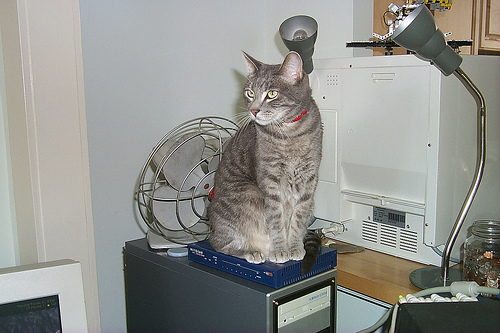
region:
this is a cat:
[191, 39, 353, 288]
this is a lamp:
[384, 5, 469, 95]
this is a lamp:
[262, 3, 351, 88]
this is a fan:
[108, 113, 280, 252]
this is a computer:
[129, 198, 371, 330]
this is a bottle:
[439, 210, 499, 290]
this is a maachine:
[304, 54, 494, 277]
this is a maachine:
[187, 234, 336, 294]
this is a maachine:
[93, 240, 323, 332]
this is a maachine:
[1, 265, 96, 331]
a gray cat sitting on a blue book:
[207, 50, 322, 276]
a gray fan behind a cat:
[131, 115, 241, 249]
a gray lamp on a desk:
[390, 5, 487, 286]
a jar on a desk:
[462, 221, 499, 288]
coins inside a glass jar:
[461, 243, 499, 290]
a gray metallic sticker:
[371, 204, 410, 232]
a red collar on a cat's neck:
[288, 105, 313, 124]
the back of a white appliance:
[311, 55, 498, 266]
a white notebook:
[338, 283, 393, 331]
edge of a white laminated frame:
[3, 260, 88, 332]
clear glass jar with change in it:
[463, 221, 497, 294]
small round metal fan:
[133, 115, 237, 247]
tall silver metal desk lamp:
[389, 3, 485, 289]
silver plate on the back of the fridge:
[371, 204, 404, 227]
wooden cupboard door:
[469, 0, 498, 54]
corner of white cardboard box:
[1, 258, 87, 331]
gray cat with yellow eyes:
[207, 49, 324, 272]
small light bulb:
[293, 29, 306, 38]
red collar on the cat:
[288, 108, 306, 121]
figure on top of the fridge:
[344, 4, 471, 54]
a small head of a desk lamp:
[386, 0, 464, 78]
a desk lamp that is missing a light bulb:
[272, 15, 337, 75]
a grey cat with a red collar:
[205, 58, 341, 265]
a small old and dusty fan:
[127, 115, 254, 254]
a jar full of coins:
[458, 215, 498, 293]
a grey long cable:
[353, 279, 496, 331]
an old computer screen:
[2, 251, 102, 331]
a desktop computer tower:
[118, 239, 349, 329]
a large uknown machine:
[263, 43, 493, 263]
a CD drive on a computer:
[271, 281, 336, 326]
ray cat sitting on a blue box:
[212, 51, 324, 273]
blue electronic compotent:
[187, 240, 336, 285]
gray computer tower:
[126, 241, 336, 331]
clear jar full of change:
[461, 221, 498, 282]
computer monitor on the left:
[0, 261, 88, 331]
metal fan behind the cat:
[134, 116, 239, 239]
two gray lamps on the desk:
[277, 7, 485, 289]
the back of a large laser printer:
[310, 60, 498, 263]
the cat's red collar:
[288, 108, 309, 123]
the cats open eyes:
[244, 87, 277, 99]